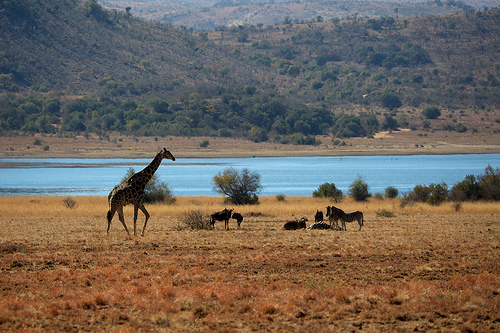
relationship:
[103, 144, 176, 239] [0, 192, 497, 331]
giraffe on ground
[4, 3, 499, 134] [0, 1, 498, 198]
hill in horizon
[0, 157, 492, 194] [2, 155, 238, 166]
water has wave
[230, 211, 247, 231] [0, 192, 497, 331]
animal on ground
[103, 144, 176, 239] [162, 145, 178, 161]
giraffe has head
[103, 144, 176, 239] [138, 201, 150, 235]
giraffe has leg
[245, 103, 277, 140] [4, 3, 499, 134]
tree on hill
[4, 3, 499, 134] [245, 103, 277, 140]
hill covered by tree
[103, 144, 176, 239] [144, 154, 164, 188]
giraffe has neck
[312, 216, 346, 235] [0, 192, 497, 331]
animal on ground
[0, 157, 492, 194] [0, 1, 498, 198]
water in horizon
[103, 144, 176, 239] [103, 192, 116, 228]
giraffe has tail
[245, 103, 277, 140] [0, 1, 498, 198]
tree in horizon